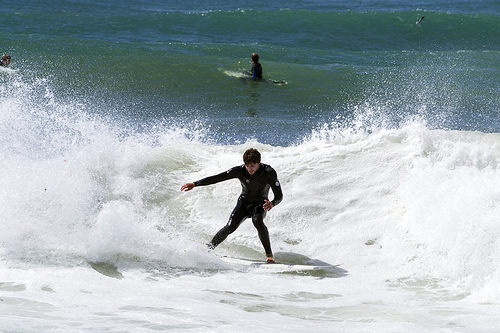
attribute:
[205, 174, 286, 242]
suit — black, wet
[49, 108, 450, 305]
water — white, calm, blue, green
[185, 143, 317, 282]
person — surfing, sitting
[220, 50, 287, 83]
person — surfing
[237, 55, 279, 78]
man — surfing, sitting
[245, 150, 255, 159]
hair — short, dark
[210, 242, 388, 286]
board — white